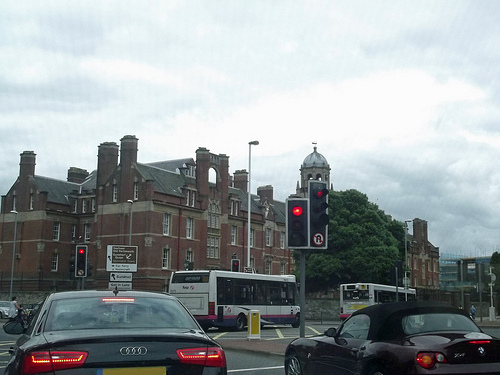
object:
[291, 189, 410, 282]
tree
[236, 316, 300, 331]
wheels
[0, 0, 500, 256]
sky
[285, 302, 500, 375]
car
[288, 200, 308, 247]
traffic light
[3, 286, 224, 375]
car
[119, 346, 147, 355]
symbol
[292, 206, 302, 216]
light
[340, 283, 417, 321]
vehicle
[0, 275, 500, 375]
street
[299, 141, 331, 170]
building top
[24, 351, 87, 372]
rear light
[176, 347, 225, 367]
rear light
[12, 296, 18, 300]
head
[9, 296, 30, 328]
person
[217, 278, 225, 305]
window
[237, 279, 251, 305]
window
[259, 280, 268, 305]
window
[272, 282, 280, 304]
window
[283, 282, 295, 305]
window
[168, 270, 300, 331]
bus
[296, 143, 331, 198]
tower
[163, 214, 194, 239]
two windows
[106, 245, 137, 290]
signs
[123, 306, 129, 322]
pole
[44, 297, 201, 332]
window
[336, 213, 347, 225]
leaves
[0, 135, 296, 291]
building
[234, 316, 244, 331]
tire